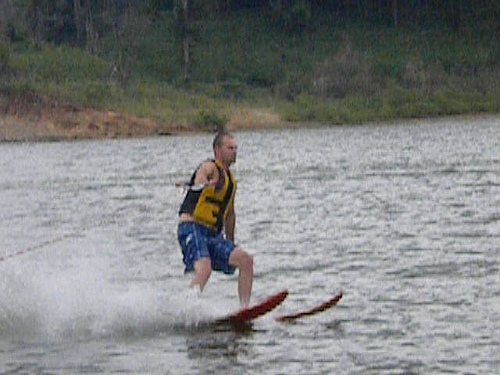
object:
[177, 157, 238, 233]
life vest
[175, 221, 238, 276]
shorts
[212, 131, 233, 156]
hair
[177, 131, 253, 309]
man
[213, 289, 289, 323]
skis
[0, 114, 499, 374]
water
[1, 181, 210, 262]
cable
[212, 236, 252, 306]
legs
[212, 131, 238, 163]
head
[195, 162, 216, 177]
arm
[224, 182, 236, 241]
other arm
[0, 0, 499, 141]
trees